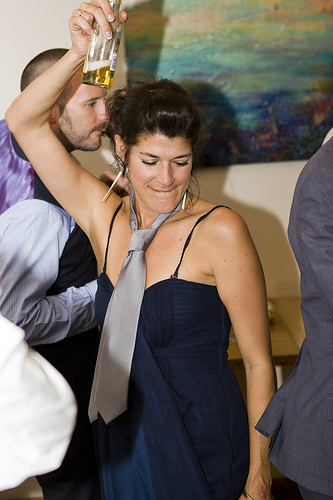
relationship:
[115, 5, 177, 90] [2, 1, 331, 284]
shadow on wall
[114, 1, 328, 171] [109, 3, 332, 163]
painting on wall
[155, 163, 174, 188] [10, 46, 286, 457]
nose on woman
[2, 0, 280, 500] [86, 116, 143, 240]
woman wearing earring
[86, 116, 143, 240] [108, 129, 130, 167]
earring in ear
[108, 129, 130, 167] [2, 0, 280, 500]
ear of woman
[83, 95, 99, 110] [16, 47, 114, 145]
eye of man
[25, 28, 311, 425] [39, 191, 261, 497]
woman wearing dress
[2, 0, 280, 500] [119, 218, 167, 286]
woman wearing tie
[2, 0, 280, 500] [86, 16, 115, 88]
woman carrying bottle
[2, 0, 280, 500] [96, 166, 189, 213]
woman wearing gold earrings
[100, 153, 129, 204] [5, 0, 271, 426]
earring dangling woman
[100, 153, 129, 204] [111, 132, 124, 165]
earring dangling ear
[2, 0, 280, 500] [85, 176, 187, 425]
woman wears gray tie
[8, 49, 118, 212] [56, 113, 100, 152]
man has beard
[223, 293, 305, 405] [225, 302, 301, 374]
desk on background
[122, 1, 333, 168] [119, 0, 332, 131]
painting on wall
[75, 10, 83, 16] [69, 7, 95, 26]
ring on finger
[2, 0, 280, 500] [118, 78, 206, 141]
woman has brown hair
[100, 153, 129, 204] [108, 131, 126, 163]
earring on ear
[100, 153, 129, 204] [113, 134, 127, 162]
earring on ear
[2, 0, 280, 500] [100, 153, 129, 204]
woman has earring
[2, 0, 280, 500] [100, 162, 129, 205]
woman has white earring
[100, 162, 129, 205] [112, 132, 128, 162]
white earring on ear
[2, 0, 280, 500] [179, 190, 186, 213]
woman wears earing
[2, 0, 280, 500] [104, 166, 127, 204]
woman wears earing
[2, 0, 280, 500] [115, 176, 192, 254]
woman wears tie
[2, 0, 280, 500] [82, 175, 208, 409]
woman wears tie